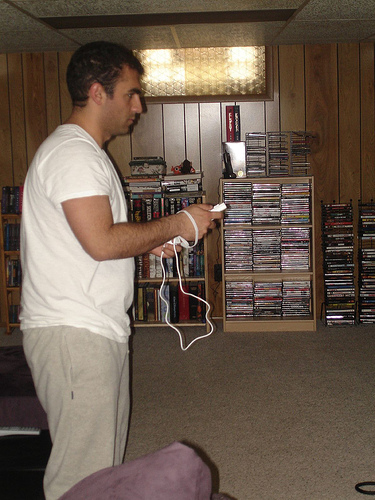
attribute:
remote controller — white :
[1, 409, 51, 443]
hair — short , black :
[63, 35, 144, 109]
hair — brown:
[72, 52, 102, 76]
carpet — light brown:
[259, 365, 294, 425]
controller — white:
[182, 196, 232, 224]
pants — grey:
[28, 325, 141, 499]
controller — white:
[155, 169, 256, 271]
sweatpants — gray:
[20, 324, 132, 499]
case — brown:
[214, 170, 325, 333]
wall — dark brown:
[1, 39, 373, 320]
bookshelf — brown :
[125, 189, 213, 331]